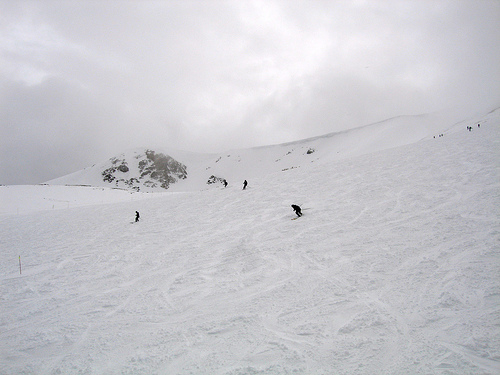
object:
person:
[289, 200, 306, 220]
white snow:
[171, 220, 310, 285]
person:
[242, 178, 249, 192]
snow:
[220, 239, 242, 254]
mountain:
[0, 103, 499, 281]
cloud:
[221, 31, 276, 64]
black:
[133, 208, 147, 221]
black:
[242, 178, 249, 193]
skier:
[219, 176, 231, 188]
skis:
[293, 214, 307, 221]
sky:
[14, 4, 484, 95]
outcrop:
[87, 150, 199, 192]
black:
[290, 201, 304, 219]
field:
[183, 223, 284, 252]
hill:
[0, 115, 499, 317]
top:
[124, 146, 166, 158]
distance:
[265, 163, 322, 178]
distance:
[221, 177, 230, 187]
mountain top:
[385, 106, 499, 148]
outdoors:
[289, 201, 303, 217]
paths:
[13, 244, 124, 303]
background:
[0, 0, 499, 115]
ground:
[0, 253, 115, 291]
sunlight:
[264, 58, 316, 84]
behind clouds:
[252, 62, 305, 96]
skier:
[468, 124, 472, 133]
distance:
[367, 118, 421, 132]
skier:
[474, 119, 483, 129]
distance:
[430, 132, 485, 147]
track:
[309, 197, 333, 214]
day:
[25, 6, 469, 96]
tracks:
[385, 177, 421, 205]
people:
[127, 210, 143, 222]